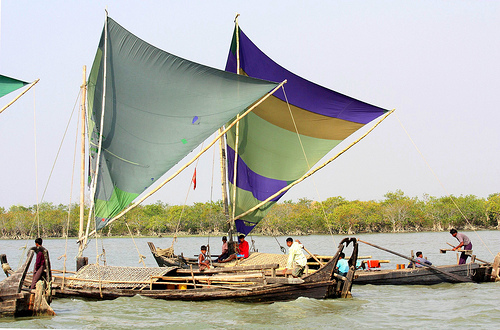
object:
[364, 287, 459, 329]
river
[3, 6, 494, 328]
outside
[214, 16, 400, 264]
sail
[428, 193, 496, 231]
trees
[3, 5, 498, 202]
sky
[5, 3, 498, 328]
sunny day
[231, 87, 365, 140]
brown stripe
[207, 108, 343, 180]
green stripe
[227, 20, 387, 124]
trim